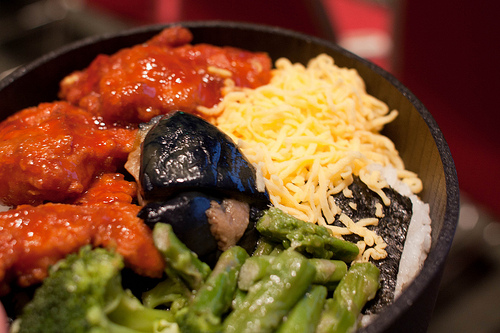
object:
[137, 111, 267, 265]
food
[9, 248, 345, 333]
food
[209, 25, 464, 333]
rim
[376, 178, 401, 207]
ground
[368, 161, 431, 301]
rice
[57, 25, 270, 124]
chicken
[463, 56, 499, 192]
ground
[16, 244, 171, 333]
broccoli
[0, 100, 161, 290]
chicken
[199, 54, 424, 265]
cheddar cheese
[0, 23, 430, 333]
food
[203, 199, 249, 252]
brown sauce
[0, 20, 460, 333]
bowl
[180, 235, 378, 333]
green beans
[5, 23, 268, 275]
chicken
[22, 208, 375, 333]
food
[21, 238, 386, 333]
vegetables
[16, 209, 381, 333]
asparagus